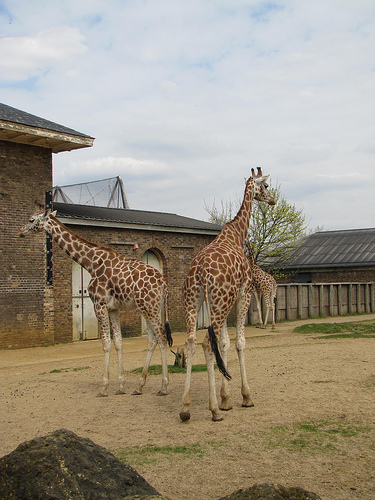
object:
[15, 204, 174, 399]
giraffe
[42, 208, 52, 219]
ears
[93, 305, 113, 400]
front legs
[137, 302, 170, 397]
back legs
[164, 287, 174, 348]
tail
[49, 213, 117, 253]
mane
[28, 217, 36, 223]
eye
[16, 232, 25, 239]
mouth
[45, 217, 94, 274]
neck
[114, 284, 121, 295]
spots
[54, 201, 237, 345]
building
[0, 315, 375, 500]
dirt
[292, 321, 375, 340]
grass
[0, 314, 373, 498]
ground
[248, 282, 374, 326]
fence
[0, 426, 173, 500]
boulder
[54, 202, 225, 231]
roof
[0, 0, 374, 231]
sky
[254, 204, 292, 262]
tree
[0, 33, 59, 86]
clouds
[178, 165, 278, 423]
giraffe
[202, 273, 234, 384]
tail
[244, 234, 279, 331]
giraffe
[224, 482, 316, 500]
pile of dirt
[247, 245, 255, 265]
neck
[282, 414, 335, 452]
grass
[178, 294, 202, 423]
legs